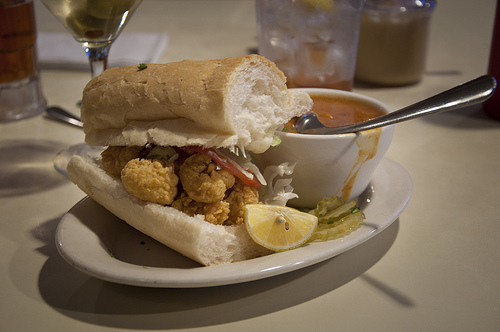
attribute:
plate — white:
[55, 153, 413, 289]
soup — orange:
[289, 92, 383, 131]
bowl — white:
[243, 86, 398, 208]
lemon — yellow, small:
[242, 201, 317, 251]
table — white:
[2, 1, 499, 328]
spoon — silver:
[296, 72, 496, 136]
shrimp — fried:
[122, 157, 178, 204]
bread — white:
[81, 53, 315, 152]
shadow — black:
[36, 216, 415, 331]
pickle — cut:
[310, 195, 364, 242]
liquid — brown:
[0, 0, 38, 82]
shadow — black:
[0, 137, 75, 197]